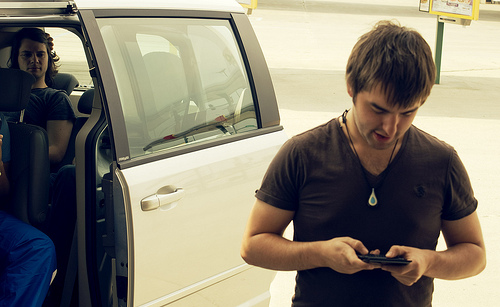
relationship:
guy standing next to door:
[6, 27, 75, 160] [2, 17, 182, 305]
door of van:
[2, 17, 182, 305] [6, 0, 289, 303]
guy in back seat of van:
[239, 18, 485, 307] [6, 0, 289, 303]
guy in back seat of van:
[6, 27, 75, 160] [6, 0, 289, 303]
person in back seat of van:
[0, 86, 61, 303] [6, 0, 289, 303]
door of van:
[70, 0, 285, 306] [6, 0, 289, 303]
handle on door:
[141, 188, 184, 210] [70, 0, 285, 306]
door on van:
[70, 0, 285, 306] [6, 0, 289, 303]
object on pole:
[418, 0, 479, 26] [430, 21, 450, 83]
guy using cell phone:
[6, 27, 75, 160] [356, 254, 412, 266]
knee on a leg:
[2, 212, 51, 305] [0, 213, 61, 303]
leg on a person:
[0, 213, 61, 303] [6, 204, 60, 302]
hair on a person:
[40, 34, 73, 71] [7, 33, 79, 211]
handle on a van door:
[135, 186, 179, 214] [78, 0, 278, 305]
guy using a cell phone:
[6, 27, 75, 160] [357, 250, 414, 270]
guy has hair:
[6, 27, 75, 160] [347, 18, 435, 109]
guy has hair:
[6, 27, 75, 160] [4, 24, 60, 78]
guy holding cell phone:
[6, 27, 75, 160] [351, 242, 416, 274]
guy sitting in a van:
[6, 27, 75, 160] [6, 0, 289, 303]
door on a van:
[70, 0, 285, 306] [0, 10, 308, 304]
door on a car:
[70, 0, 285, 306] [4, 0, 293, 303]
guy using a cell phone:
[6, 27, 75, 160] [351, 246, 415, 269]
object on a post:
[426, 2, 479, 26] [431, 24, 447, 79]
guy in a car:
[6, 27, 75, 160] [4, 0, 293, 303]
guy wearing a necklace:
[6, 27, 75, 160] [349, 120, 413, 220]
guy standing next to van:
[302, 44, 484, 241] [49, 0, 306, 298]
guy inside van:
[4, 24, 75, 201] [6, 0, 289, 303]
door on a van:
[79, 3, 281, 296] [6, 0, 289, 303]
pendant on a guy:
[366, 185, 380, 205] [239, 18, 485, 307]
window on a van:
[84, 8, 286, 150] [6, 0, 289, 303]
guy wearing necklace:
[239, 18, 485, 307] [341, 104, 401, 208]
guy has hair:
[239, 18, 485, 307] [348, 15, 443, 104]